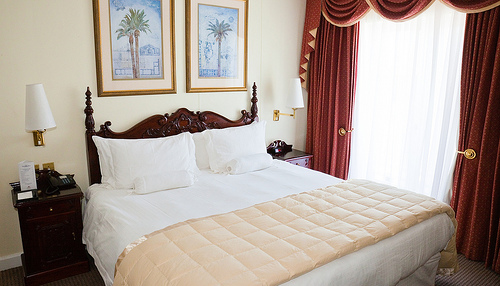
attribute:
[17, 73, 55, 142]
shad — white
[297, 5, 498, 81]
valance — red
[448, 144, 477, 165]
curtain tieback — metal, gold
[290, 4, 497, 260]
curtains — gold, red, window, fancy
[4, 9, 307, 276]
wall — white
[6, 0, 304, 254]
wall — white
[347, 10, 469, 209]
panel — white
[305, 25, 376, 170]
curtain — red 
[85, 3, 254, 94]
pictures — matted, framed 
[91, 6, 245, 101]
palms — framed , matted 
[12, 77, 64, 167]
lamp — attached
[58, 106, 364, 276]
bed — made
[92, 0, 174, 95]
frame — gold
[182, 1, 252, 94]
frame — gold